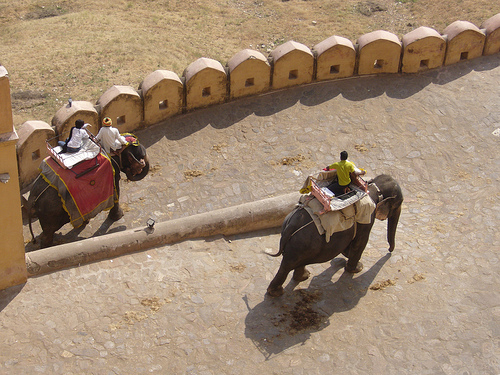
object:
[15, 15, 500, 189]
pen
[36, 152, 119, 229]
blanket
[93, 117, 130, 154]
people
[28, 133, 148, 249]
elephant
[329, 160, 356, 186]
shirt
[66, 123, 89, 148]
shirt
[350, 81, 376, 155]
concrete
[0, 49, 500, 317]
ground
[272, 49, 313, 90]
wall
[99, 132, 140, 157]
cloth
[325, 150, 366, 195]
man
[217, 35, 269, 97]
pillsa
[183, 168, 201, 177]
dirt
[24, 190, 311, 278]
post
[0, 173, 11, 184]
light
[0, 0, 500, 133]
grass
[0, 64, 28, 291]
pole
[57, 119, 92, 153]
boy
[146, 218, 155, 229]
divider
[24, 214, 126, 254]
shadow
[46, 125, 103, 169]
basket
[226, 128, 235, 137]
stones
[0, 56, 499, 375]
walkway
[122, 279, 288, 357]
sand